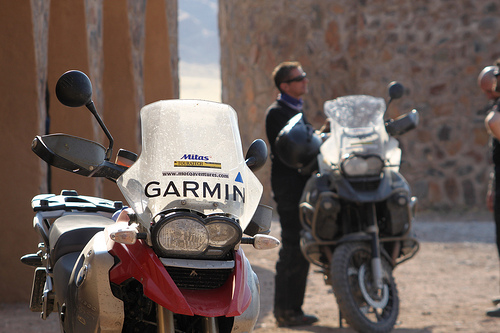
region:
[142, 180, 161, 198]
the letter g on plastic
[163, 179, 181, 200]
the letter a on plastic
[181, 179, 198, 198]
the letter r on plastic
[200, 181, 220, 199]
the letter m on plastic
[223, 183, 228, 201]
the letter i on plastic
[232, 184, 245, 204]
the letter n on plastic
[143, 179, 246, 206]
the word "garmin" printed on plastic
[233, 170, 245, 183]
a blue triangle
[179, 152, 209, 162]
"mitas" logo printed on plastic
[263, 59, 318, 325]
man standing next to motercycle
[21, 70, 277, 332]
white and red motorcycle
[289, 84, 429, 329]
black motorcycle on ground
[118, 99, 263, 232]
white wind shield on bike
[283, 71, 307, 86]
black sun glasses on face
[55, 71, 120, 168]
side mirror on bike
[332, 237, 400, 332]
black tire on bike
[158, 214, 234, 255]
head light on bike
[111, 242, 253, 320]
red fender on bike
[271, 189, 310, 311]
black cotton denim jeans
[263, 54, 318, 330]
man wearing black jacket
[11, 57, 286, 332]
The motorcycle is parked.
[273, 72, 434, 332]
The motorcycle is parked.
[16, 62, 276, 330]
The motorcycle is unattended.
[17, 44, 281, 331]
The motorcycle is vacant.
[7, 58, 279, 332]
The motorcycle is unoccupied.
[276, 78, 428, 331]
The motorcycle is unoccupied.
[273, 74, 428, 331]
A helmet is hanging on the motorcycle.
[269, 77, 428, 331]
The motorcycle is black.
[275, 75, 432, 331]
The motorcycle is leaning on its kickstand.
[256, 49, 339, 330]
The man is wearing sunglasses.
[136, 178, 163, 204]
The letter is black.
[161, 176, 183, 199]
The letter is black.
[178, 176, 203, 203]
The letter is black.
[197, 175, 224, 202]
The letter is black.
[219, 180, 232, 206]
The letter is black.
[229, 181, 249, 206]
The letter is black.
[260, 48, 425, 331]
The man is standing next to the motorcycle.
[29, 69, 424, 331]
front of two parked motorbikes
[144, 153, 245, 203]
logos on bike windshield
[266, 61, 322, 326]
man next to motorbike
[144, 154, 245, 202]
logos on windshield surface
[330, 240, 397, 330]
turned tire of bike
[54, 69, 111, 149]
back of side view mirror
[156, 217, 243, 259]
lights on front of bike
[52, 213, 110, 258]
seat on top of bike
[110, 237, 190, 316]
red piece of fiberglass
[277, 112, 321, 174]
helmet on side of bike